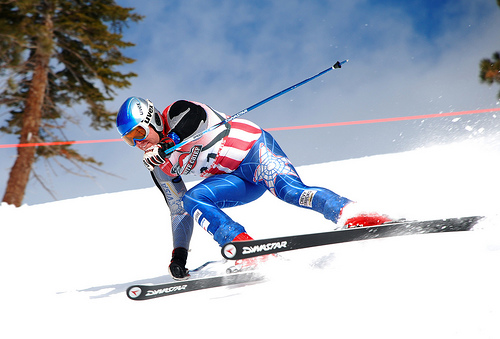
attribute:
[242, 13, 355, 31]
sky — blue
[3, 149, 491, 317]
snow — white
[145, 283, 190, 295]
letters — white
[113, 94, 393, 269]
person — skiing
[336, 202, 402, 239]
shoe — pair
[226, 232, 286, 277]
shoe — pair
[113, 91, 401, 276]
suit — ski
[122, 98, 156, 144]
goggles — white, snow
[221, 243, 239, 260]
design — circular, red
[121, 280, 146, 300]
design — red, circular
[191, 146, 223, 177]
race bib — white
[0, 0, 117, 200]
trunk — tree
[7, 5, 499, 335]
picture — outdoors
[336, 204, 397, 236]
foot — man's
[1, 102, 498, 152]
red light — long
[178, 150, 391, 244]
pants — blue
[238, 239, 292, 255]
print — white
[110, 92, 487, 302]
person — skiing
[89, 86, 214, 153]
helmet — silver, blue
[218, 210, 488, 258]
ski — black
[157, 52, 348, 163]
ski pole — blue